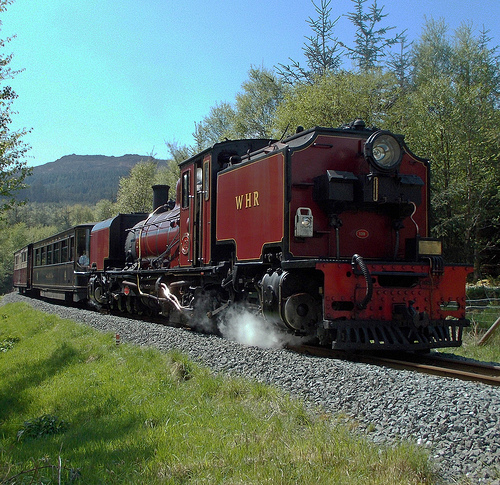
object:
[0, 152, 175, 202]
mountains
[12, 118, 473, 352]
locomotive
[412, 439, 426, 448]
place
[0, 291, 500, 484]
gravel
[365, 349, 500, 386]
tracks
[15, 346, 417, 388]
floor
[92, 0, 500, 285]
forest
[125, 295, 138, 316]
wheels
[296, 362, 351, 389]
stones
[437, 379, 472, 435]
stones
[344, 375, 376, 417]
stones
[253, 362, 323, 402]
stones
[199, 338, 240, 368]
stones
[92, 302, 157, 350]
stones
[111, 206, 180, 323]
engine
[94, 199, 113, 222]
trees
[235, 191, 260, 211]
words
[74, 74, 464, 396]
train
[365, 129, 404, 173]
headlight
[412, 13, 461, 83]
trees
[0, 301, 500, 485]
grass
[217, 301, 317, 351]
smoke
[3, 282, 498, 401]
tracks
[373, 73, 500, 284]
tree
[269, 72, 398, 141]
tree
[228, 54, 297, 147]
tree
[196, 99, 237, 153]
tree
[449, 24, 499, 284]
tree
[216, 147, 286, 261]
plate